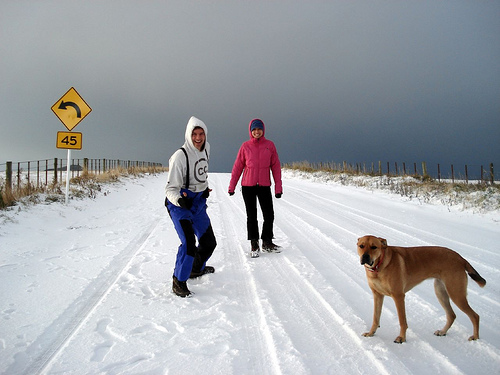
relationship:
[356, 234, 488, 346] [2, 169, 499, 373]
dog in snow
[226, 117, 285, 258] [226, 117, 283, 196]
woman wearing jacket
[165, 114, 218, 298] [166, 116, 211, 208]
man wearing jacket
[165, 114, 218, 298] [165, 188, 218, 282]
man wearing pants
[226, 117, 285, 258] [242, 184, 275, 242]
woman wearing pants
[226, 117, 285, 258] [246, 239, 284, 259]
woman wearing boots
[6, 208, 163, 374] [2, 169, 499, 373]
tire track in snow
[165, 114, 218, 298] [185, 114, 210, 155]
man wearing hood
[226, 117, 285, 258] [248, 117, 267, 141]
woman wearing hood and hat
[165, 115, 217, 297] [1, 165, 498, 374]
man on snow covered road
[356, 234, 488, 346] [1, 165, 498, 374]
dog on snow covered road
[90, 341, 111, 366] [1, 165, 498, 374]
footprint in snow covered road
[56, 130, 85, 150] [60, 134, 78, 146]
sign with 45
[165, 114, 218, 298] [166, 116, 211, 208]
person in hoodie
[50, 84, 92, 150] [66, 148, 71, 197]
street signs on pole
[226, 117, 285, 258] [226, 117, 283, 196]
woman in coat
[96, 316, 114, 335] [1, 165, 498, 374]
footprint in snow covered road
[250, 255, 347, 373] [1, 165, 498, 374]
tire track in snow covered road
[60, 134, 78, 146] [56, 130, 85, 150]
45 on sign